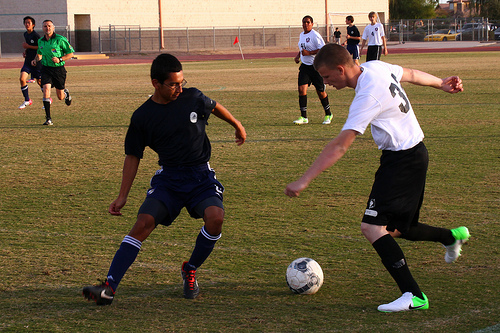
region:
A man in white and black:
[285, 47, 485, 322]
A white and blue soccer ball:
[264, 237, 346, 310]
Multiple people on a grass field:
[14, 8, 486, 324]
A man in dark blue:
[83, 41, 250, 301]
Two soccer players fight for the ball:
[91, 38, 483, 315]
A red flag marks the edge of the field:
[211, 24, 264, 94]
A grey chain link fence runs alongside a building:
[77, 15, 424, 53]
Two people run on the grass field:
[7, 5, 87, 129]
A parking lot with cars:
[386, 7, 498, 55]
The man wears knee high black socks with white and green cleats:
[281, 48, 478, 330]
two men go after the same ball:
[96, 51, 482, 328]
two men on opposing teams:
[127, 56, 462, 302]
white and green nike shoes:
[354, 214, 491, 331]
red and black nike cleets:
[91, 163, 230, 328]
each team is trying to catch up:
[11, 16, 428, 142]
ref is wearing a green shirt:
[24, 19, 84, 142]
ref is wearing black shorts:
[23, 19, 80, 136]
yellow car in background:
[420, 22, 490, 135]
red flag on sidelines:
[214, 29, 276, 99]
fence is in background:
[84, 19, 373, 78]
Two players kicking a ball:
[132, 43, 423, 299]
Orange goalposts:
[150, 7, 338, 53]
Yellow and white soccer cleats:
[368, 279, 437, 313]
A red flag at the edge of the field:
[223, 30, 257, 64]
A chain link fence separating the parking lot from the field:
[396, 10, 496, 47]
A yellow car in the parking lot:
[414, 16, 465, 46]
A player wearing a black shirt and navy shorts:
[116, 80, 247, 215]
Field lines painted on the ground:
[16, 215, 301, 308]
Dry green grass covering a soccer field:
[240, 117, 365, 192]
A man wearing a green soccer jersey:
[30, 20, 78, 83]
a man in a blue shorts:
[81, 50, 251, 303]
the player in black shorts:
[276, 44, 481, 309]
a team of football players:
[0, 9, 497, 316]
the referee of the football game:
[31, 14, 96, 125]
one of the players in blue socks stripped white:
[71, 225, 241, 303]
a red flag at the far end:
[228, 31, 255, 68]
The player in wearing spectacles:
[83, 52, 260, 302]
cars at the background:
[396, 0, 496, 50]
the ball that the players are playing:
[281, 248, 328, 300]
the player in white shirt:
[287, 40, 471, 322]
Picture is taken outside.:
[0, 21, 472, 268]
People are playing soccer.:
[13, 10, 450, 246]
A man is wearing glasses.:
[154, 62, 194, 102]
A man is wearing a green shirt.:
[25, 32, 112, 67]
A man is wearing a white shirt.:
[327, 37, 426, 172]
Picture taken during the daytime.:
[72, 23, 364, 178]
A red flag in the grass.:
[225, 25, 252, 66]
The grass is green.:
[27, 142, 91, 274]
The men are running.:
[6, 7, 91, 140]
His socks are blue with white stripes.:
[88, 219, 234, 256]